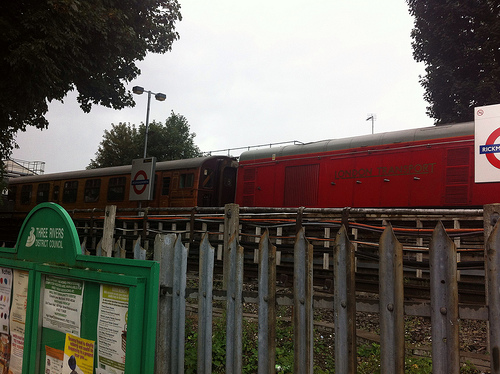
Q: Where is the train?
A: On a bridge.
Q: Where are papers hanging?
A: Under glass.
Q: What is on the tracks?
A: Two car train.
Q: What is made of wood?
A: Fence.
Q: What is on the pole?
A: Lights.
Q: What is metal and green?
A: Board.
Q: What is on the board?
A: Public notices.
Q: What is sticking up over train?
A: Tree.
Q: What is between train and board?
A: Picket fence.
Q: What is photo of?
A: Train.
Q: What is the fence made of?
A: Wood.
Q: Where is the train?
A: Behind the fence.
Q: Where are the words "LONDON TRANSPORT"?
A: On the red train car.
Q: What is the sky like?
A: Clouded.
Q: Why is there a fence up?
A: Safety.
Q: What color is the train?
A: Red.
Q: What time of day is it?
A: Daytime.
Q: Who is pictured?
A: No one.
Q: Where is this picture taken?
A: Outside tracks.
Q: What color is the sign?
A: Green.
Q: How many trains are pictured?
A: One.